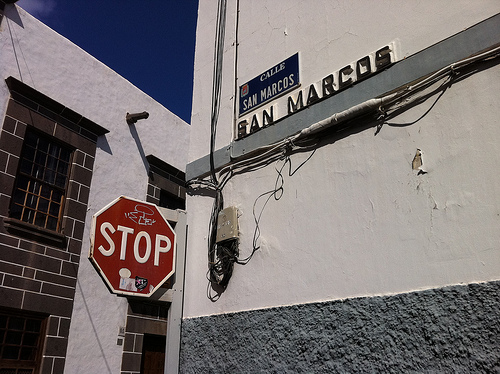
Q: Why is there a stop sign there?
A: It's hanging there.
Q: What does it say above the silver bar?
A: San Marcos.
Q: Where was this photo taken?
A: In the street.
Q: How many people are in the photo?
A: Zero.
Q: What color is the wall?
A: Beige.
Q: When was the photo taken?
A: During the day.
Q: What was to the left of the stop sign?
A: Brick wall.